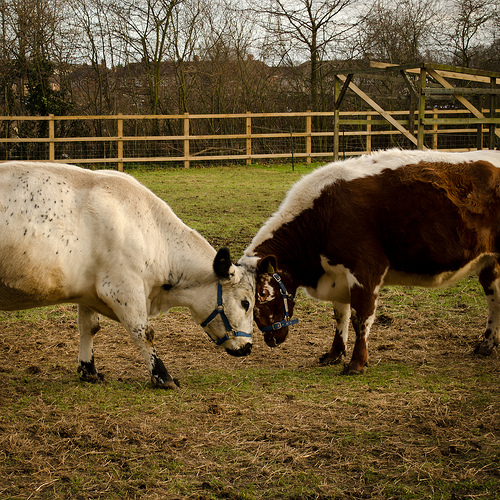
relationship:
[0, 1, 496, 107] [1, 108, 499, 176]
trees are beyond fence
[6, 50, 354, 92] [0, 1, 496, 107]
buildings are behind trees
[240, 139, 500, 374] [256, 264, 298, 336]
cow has a muzzle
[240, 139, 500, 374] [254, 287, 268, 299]
cow has an eye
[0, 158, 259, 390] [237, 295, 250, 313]
cows has an eye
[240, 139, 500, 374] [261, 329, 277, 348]
cow has a nose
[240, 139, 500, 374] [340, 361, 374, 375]
cow has a hoof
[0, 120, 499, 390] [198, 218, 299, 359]
cows have heads together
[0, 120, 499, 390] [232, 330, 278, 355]
cows have noses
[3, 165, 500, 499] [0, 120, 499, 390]
grass under cows